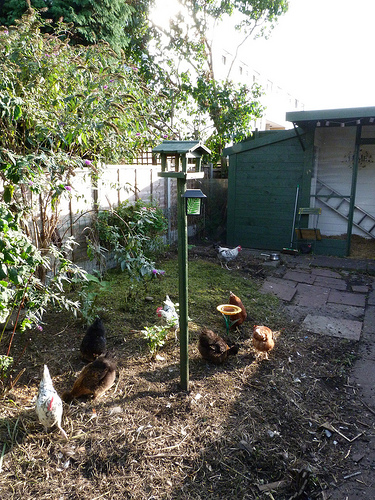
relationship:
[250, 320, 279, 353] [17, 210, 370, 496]
chicken in yard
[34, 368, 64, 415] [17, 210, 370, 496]
chicken in yard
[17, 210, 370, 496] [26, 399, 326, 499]
yard has mulch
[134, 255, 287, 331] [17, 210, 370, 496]
grass in yard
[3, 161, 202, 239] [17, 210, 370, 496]
fence on side of yard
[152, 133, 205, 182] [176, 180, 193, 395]
feeder on top of pole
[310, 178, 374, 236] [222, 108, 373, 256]
ladder leaning against building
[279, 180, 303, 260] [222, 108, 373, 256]
broom leaning against building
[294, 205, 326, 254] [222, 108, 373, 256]
chair leaning against building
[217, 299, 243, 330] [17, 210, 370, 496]
pot in yard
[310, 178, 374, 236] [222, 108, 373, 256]
ladder propped on building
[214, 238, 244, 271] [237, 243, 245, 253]
chicken has head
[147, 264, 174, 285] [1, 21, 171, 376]
flowers on tree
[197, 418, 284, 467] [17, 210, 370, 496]
straw on yard